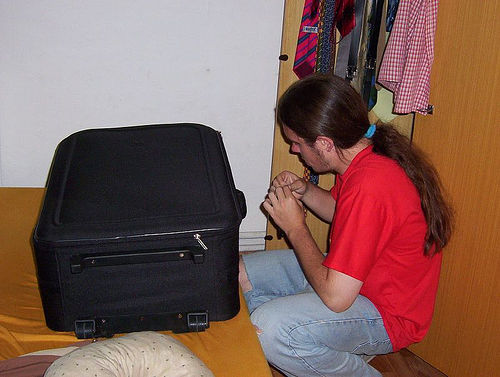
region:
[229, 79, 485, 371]
An unkempt man picking at his finger nails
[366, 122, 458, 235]
A long pony tail on the man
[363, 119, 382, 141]
A blue hair band in the man's hair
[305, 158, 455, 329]
A red shirt on the man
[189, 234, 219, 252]
A small metal zipper on the suitcase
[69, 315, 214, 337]
Two black wheels on the suitcase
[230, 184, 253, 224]
The black handle of the suitcase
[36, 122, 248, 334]
A large black suitcase on the table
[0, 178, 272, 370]
A wooden table beneath the suitcase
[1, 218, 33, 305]
The table is made of wood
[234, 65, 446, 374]
Young man kneeling on the floor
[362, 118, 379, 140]
Blue hair band around man's ponytail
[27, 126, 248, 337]
Black suitecase laying on the bed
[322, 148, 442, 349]
Red tee shirt man is wearing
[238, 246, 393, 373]
Man wearing light colored blue jeans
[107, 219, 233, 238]
Zipper of black suitcase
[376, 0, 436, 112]
Red and white shirt hanging on the wall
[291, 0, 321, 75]
Red and black necktie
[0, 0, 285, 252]
White wall in back of the bed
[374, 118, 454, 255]
Man's brown ponytail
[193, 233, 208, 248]
The metallic zipper handle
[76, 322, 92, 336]
The suitcase castor wheel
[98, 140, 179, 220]
The top surface of a suitcase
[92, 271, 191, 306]
The bottom of a suitcase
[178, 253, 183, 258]
A metal pin sticking into suitcase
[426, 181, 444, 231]
Pony tail on the back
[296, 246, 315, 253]
Hair on the foream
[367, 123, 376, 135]
A blue strap around the hair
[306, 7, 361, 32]
Ties hanging on the door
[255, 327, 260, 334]
A hole in the jeans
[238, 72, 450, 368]
the man is squatting down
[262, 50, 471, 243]
the man has long hair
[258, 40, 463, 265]
man is wearing a ponytail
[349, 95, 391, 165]
the holder is blue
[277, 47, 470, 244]
the man has brown hair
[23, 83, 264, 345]
a black suit case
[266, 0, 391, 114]
ties on the door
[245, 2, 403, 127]
the door is open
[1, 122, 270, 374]
suitcase is on the bed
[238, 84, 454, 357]
man wearing a red shirt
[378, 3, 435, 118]
a red plaid shirt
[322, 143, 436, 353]
an orangish-red short sleeve shirt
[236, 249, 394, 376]
a pair of blue jeans with rip at right knee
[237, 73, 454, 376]
a guy squating down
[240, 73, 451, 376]
a guy with a long pony tail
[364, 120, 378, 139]
a light blue pony tail band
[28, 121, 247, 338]
a black suitcase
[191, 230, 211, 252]
a silver zipper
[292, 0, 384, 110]
ties hanging up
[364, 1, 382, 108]
a black belt